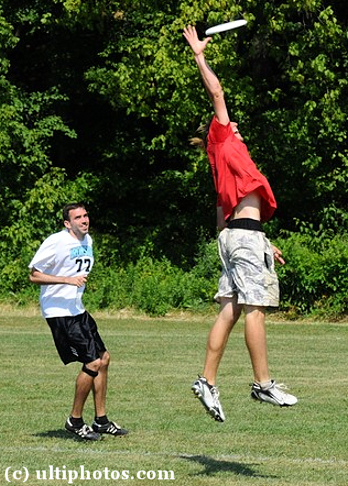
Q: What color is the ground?
A: Green.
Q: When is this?
A: Daytime.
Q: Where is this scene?
A: In a grassy green field.